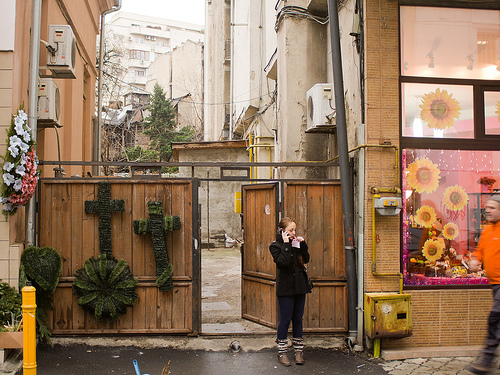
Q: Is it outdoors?
A: Yes, it is outdoors.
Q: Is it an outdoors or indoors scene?
A: It is outdoors.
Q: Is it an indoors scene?
A: No, it is outdoors.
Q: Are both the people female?
A: No, they are both male and female.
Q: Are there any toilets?
A: No, there are no toilets.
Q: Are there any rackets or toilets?
A: No, there are no toilets or rackets.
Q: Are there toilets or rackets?
A: No, there are no toilets or rackets.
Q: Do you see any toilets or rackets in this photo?
A: No, there are no toilets or rackets.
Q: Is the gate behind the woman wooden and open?
A: Yes, the gate is wooden and open.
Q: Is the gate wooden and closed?
A: No, the gate is wooden but open.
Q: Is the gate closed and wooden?
A: No, the gate is wooden but open.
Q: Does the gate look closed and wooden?
A: No, the gate is wooden but open.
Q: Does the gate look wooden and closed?
A: No, the gate is wooden but open.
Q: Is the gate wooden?
A: Yes, the gate is wooden.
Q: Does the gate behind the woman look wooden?
A: Yes, the gate is wooden.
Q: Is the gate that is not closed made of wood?
A: Yes, the gate is made of wood.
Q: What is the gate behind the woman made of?
A: The gate is made of wood.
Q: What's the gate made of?
A: The gate is made of wood.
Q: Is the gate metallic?
A: No, the gate is wooden.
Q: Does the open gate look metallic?
A: No, the gate is wooden.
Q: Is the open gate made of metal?
A: No, the gate is made of wood.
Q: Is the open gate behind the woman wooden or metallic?
A: The gate is wooden.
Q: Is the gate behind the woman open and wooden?
A: Yes, the gate is open and wooden.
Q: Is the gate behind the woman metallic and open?
A: No, the gate is open but wooden.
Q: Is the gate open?
A: Yes, the gate is open.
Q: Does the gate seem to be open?
A: Yes, the gate is open.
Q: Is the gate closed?
A: No, the gate is open.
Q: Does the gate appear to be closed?
A: No, the gate is open.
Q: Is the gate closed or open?
A: The gate is open.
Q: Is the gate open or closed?
A: The gate is open.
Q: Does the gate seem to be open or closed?
A: The gate is open.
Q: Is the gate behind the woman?
A: Yes, the gate is behind the woman.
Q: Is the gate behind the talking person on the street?
A: Yes, the gate is behind the woman.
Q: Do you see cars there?
A: No, there are no cars.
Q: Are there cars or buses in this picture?
A: No, there are no cars or buses.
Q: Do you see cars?
A: No, there are no cars.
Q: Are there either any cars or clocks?
A: No, there are no cars or clocks.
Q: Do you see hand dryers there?
A: No, there are no hand dryers.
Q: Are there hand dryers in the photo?
A: No, there are no hand dryers.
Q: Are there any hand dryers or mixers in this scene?
A: No, there are no hand dryers or mixers.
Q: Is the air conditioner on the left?
A: Yes, the air conditioner is on the left of the image.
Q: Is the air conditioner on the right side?
A: No, the air conditioner is on the left of the image.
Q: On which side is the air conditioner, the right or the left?
A: The air conditioner is on the left of the image.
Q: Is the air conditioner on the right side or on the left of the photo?
A: The air conditioner is on the left of the image.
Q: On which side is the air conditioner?
A: The air conditioner is on the left of the image.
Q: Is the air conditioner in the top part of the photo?
A: Yes, the air conditioner is in the top of the image.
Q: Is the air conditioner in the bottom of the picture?
A: No, the air conditioner is in the top of the image.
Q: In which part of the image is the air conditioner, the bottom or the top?
A: The air conditioner is in the top of the image.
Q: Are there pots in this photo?
A: No, there are no pots.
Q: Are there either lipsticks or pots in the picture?
A: No, there are no pots or lipsticks.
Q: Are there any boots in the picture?
A: Yes, there are boots.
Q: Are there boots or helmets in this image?
A: Yes, there are boots.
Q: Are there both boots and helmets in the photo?
A: No, there are boots but no helmets.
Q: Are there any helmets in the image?
A: No, there are no helmets.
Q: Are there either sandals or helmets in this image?
A: No, there are no helmets or sandals.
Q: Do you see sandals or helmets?
A: No, there are no helmets or sandals.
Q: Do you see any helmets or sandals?
A: No, there are no helmets or sandals.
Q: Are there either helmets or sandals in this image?
A: No, there are no helmets or sandals.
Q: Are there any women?
A: Yes, there is a woman.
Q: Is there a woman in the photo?
A: Yes, there is a woman.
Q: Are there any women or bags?
A: Yes, there is a woman.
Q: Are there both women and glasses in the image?
A: No, there is a woman but no glasses.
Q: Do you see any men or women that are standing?
A: Yes, the woman is standing.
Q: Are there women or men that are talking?
A: Yes, the woman is talking.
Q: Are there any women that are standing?
A: Yes, there is a woman that is standing.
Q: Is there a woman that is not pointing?
A: Yes, there is a woman that is standing.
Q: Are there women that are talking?
A: Yes, there is a woman that is talking.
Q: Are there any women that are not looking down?
A: Yes, there is a woman that is talking.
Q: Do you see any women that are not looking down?
A: Yes, there is a woman that is talking .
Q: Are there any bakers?
A: No, there are no bakers.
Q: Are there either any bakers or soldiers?
A: No, there are no bakers or soldiers.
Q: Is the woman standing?
A: Yes, the woman is standing.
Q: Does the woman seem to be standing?
A: Yes, the woman is standing.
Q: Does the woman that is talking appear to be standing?
A: Yes, the woman is standing.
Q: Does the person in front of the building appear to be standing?
A: Yes, the woman is standing.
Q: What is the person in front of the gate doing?
A: The woman is standing.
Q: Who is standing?
A: The woman is standing.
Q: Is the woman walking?
A: No, the woman is standing.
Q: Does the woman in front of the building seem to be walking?
A: No, the woman is standing.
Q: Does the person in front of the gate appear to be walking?
A: No, the woman is standing.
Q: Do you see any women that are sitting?
A: No, there is a woman but she is standing.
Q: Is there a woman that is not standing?
A: No, there is a woman but she is standing.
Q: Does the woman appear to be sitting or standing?
A: The woman is standing.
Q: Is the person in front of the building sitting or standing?
A: The woman is standing.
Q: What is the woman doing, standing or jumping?
A: The woman is standing.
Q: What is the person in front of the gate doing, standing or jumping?
A: The woman is standing.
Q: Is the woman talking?
A: Yes, the woman is talking.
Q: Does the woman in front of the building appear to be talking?
A: Yes, the woman is talking.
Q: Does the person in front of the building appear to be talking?
A: Yes, the woman is talking.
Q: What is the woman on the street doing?
A: The woman is talking.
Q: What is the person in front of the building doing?
A: The woman is talking.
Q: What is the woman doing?
A: The woman is talking.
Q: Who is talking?
A: The woman is talking.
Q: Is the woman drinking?
A: No, the woman is talking.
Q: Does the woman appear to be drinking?
A: No, the woman is talking.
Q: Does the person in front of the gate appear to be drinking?
A: No, the woman is talking.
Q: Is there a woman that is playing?
A: No, there is a woman but she is talking.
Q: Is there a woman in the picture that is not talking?
A: No, there is a woman but she is talking.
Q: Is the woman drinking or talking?
A: The woman is talking.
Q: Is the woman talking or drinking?
A: The woman is talking.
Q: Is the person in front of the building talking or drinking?
A: The woman is talking.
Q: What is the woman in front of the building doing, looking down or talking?
A: The woman is talking.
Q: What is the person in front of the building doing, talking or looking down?
A: The woman is talking.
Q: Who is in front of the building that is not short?
A: The woman is in front of the building.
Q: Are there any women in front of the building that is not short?
A: Yes, there is a woman in front of the building.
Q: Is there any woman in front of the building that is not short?
A: Yes, there is a woman in front of the building.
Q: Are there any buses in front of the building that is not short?
A: No, there is a woman in front of the building.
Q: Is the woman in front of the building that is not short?
A: Yes, the woman is in front of the building.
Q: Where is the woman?
A: The woman is on the street.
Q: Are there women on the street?
A: Yes, there is a woman on the street.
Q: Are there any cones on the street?
A: No, there is a woman on the street.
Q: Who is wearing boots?
A: The woman is wearing boots.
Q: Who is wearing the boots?
A: The woman is wearing boots.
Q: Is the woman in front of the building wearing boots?
A: Yes, the woman is wearing boots.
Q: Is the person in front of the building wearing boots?
A: Yes, the woman is wearing boots.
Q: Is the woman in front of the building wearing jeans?
A: No, the woman is wearing boots.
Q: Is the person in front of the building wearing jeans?
A: No, the woman is wearing boots.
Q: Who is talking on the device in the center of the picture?
A: The woman is talking on the cell phone.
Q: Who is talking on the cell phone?
A: The woman is talking on the cell phone.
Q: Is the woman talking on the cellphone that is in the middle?
A: Yes, the woman is talking on the mobile phone.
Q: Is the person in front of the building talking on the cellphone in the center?
A: Yes, the woman is talking on the mobile phone.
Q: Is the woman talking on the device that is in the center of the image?
A: Yes, the woman is talking on the mobile phone.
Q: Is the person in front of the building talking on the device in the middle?
A: Yes, the woman is talking on the mobile phone.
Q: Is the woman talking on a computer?
A: No, the woman is talking on the mobile phone.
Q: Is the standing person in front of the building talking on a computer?
A: No, the woman is talking on the mobile phone.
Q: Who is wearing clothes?
A: The woman is wearing clothes.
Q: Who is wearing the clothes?
A: The woman is wearing clothes.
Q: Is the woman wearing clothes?
A: Yes, the woman is wearing clothes.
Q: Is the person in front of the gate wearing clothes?
A: Yes, the woman is wearing clothes.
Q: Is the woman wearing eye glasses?
A: No, the woman is wearing clothes.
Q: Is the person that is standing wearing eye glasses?
A: No, the woman is wearing clothes.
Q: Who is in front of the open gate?
A: The woman is in front of the gate.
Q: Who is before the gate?
A: The woman is in front of the gate.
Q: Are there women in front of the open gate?
A: Yes, there is a woman in front of the gate.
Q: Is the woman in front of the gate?
A: Yes, the woman is in front of the gate.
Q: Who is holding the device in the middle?
A: The woman is holding the cell phone.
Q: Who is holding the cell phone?
A: The woman is holding the cell phone.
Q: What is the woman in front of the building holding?
A: The woman is holding the mobile phone.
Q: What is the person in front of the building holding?
A: The woman is holding the mobile phone.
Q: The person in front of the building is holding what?
A: The woman is holding the mobile phone.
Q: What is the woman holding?
A: The woman is holding the mobile phone.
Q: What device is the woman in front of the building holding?
A: The woman is holding the cell phone.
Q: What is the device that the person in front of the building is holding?
A: The device is a cell phone.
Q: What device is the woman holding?
A: The woman is holding the cell phone.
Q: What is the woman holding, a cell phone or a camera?
A: The woman is holding a cell phone.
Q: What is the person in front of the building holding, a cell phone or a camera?
A: The woman is holding a cell phone.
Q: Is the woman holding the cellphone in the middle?
A: Yes, the woman is holding the cell phone.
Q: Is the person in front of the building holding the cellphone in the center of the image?
A: Yes, the woman is holding the cell phone.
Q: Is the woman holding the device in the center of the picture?
A: Yes, the woman is holding the cell phone.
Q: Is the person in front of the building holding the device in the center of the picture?
A: Yes, the woman is holding the cell phone.